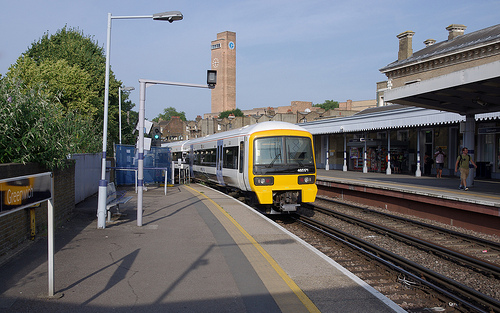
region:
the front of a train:
[216, 48, 364, 228]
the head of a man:
[451, 134, 476, 164]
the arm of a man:
[442, 143, 464, 177]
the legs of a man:
[453, 165, 475, 192]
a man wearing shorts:
[447, 145, 482, 194]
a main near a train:
[421, 132, 484, 200]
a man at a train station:
[407, 103, 498, 214]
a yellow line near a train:
[221, 198, 276, 298]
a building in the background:
[196, 25, 286, 127]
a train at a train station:
[200, 73, 407, 240]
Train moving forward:
[154, 120, 318, 222]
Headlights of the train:
[254, 173, 313, 188]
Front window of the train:
[254, 133, 316, 175]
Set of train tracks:
[276, 180, 498, 311]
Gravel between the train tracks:
[295, 182, 499, 308]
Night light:
[134, 70, 221, 224]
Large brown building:
[209, 30, 239, 116]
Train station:
[294, 20, 495, 205]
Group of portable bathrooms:
[110, 141, 176, 192]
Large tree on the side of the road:
[2, 28, 142, 171]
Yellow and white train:
[153, 115, 342, 221]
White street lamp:
[90, 1, 227, 259]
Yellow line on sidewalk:
[158, 166, 330, 312]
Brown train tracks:
[244, 163, 496, 312]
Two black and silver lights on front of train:
[252, 172, 326, 186]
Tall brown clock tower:
[200, 23, 260, 137]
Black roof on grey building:
[372, 22, 499, 82]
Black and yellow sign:
[0, 158, 74, 229]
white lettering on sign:
[0, 182, 33, 220]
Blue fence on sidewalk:
[112, 131, 185, 196]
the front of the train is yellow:
[154, 112, 359, 222]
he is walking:
[453, 137, 497, 205]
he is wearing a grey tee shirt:
[448, 136, 483, 198]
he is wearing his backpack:
[446, 140, 481, 196]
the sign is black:
[0, 168, 75, 245]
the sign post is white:
[2, 168, 74, 303]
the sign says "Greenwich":
[1, 178, 59, 214]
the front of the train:
[233, 118, 321, 231]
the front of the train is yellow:
[240, 92, 336, 244]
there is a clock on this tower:
[206, 12, 263, 143]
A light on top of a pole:
[146, 3, 192, 33]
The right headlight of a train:
[250, 171, 275, 189]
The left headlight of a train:
[295, 171, 315, 184]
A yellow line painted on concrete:
[236, 235, 294, 293]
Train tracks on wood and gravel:
[346, 202, 424, 256]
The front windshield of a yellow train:
[247, 130, 318, 177]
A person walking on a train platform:
[447, 141, 485, 194]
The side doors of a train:
[208, 137, 232, 191]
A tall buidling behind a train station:
[203, 23, 246, 130]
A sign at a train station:
[0, 168, 62, 220]